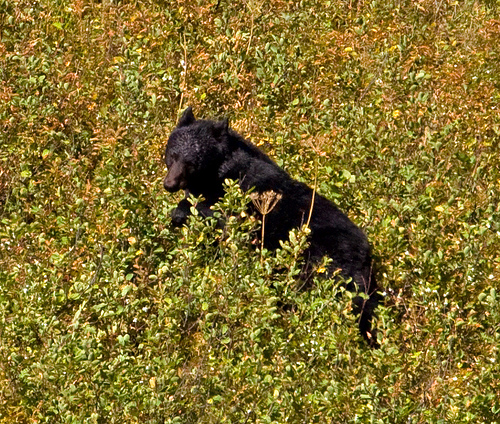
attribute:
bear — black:
[148, 108, 388, 348]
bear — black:
[153, 146, 379, 333]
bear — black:
[175, 125, 375, 333]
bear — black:
[168, 138, 392, 386]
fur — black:
[353, 285, 373, 305]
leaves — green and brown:
[83, 325, 193, 395]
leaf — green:
[477, 285, 486, 302]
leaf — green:
[200, 300, 213, 310]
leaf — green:
[409, 54, 424, 72]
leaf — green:
[20, 166, 33, 179]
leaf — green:
[115, 330, 129, 347]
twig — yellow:
[245, 190, 281, 266]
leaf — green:
[362, 370, 372, 386]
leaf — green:
[55, 395, 68, 411]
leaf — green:
[149, 89, 157, 110]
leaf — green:
[268, 385, 284, 403]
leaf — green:
[322, 382, 336, 398]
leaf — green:
[325, 379, 339, 393]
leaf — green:
[370, 348, 384, 360]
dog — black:
[150, 103, 411, 334]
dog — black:
[169, 96, 305, 302]